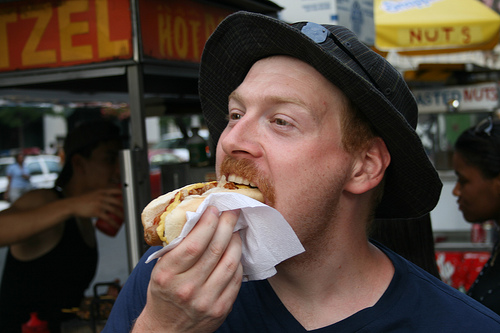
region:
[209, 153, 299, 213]
man's mouth open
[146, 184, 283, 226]
ketchup and mustard on the hot dog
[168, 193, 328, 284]
napkin around the hot dog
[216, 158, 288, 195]
man has a mustach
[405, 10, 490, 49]
NUTS written in red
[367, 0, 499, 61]
yellow cover with nuts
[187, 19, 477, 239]
man is wearing a hat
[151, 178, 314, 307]
man holding hot dog in his hand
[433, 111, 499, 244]
person standing behind man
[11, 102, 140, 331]
woman under the tent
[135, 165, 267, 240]
hot dog in hands being eaten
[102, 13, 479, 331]
guy eating hot dog with one hand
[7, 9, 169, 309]
guy selling hot dogs in stand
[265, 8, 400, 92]
sunglasses on top of hat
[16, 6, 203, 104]
yellow and red hot dog stand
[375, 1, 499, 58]
nuts umbrella for stand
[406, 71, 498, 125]
roasted nuts sign for stand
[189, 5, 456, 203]
hat on head of man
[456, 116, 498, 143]
sunglasses on top of lady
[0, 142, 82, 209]
van parked on street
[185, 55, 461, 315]
this is a man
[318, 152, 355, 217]
the man is light skinned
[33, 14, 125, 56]
this is a writing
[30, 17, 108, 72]
the writing is in yellow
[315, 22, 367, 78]
this is a hat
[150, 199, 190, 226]
this is a snack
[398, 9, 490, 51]
this is a tent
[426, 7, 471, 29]
the tent is yellow in color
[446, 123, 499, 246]
this is a lady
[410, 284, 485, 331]
this is a t shirt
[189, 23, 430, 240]
the head of a man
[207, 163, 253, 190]
the teeth of a man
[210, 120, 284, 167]
the nose of a man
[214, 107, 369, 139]
the eyes of a man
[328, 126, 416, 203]
the ear of a man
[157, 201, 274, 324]
the hand of a man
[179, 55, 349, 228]
the face of a man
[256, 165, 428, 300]
the neck of a man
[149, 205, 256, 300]
the fingers of a man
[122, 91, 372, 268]
a man eating a hot dog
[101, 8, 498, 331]
A man eating a hot dog.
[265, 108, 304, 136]
A eye on a person.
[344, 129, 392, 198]
A ear on a man.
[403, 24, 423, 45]
The letter N on a sign.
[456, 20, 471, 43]
The letter S on a sign.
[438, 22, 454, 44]
The letter T on a sign.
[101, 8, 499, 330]
A man wearing a hat.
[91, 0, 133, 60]
The letter L on a sign.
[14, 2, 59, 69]
The letter Z on a sign.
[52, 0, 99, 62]
The letter E on a sign.